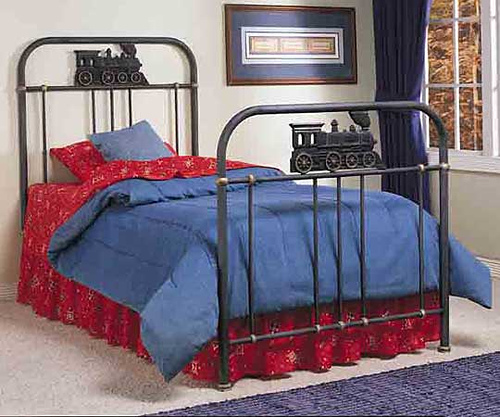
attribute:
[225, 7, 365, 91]
hanging — wall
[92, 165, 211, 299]
comforter — blue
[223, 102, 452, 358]
board — foot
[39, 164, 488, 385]
duvet — blue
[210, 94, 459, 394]
railings — metal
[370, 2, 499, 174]
window — open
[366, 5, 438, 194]
curtain — blue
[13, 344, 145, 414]
carpet — white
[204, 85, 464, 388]
rails — black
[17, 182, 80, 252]
sheet — red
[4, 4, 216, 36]
wall — white, clean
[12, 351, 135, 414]
floor — light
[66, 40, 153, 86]
train — on the headboard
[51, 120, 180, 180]
pillows — piled up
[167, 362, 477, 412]
blue rug — in front of the bed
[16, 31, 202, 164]
headboard — of the bed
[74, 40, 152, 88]
train decoration — on the headboard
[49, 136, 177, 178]
red pillow — on the bed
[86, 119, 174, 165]
blue pillow — on the bed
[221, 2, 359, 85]
picture — on the wall, hanging on the wall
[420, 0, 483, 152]
window — in the room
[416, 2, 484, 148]
blue curtains — on the window